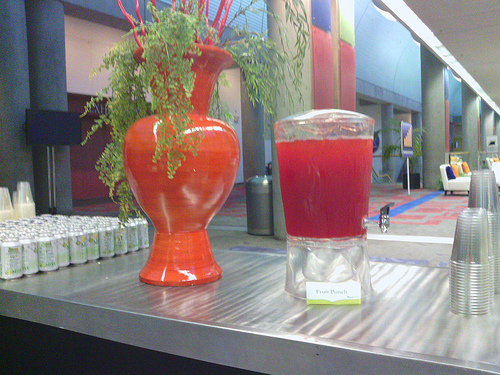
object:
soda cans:
[37, 237, 58, 274]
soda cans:
[54, 234, 71, 268]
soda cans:
[66, 232, 88, 265]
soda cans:
[20, 238, 39, 277]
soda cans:
[84, 229, 99, 262]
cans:
[0, 242, 24, 280]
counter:
[122, 239, 498, 371]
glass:
[275, 109, 376, 139]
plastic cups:
[450, 303, 490, 310]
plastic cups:
[16, 181, 35, 205]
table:
[370, 317, 495, 375]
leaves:
[150, 67, 206, 180]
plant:
[81, 0, 303, 220]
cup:
[450, 208, 492, 267]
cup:
[468, 169, 500, 216]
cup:
[450, 263, 489, 269]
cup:
[450, 308, 489, 316]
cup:
[449, 280, 490, 287]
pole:
[406, 157, 410, 195]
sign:
[400, 120, 413, 158]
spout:
[379, 202, 395, 234]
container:
[274, 109, 374, 301]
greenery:
[95, 130, 123, 218]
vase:
[124, 43, 241, 287]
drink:
[275, 137, 373, 238]